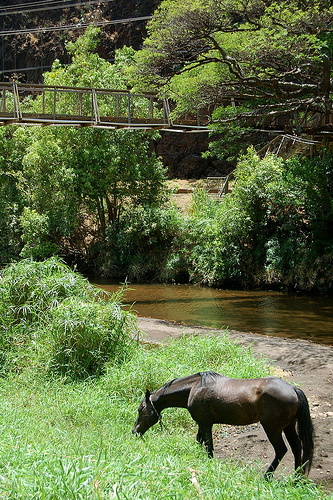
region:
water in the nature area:
[98, 277, 325, 325]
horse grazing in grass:
[131, 375, 323, 482]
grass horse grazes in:
[3, 378, 238, 492]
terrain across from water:
[98, 172, 259, 257]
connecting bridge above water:
[8, 72, 312, 123]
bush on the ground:
[1, 257, 138, 375]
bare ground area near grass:
[147, 328, 332, 465]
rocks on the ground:
[237, 432, 332, 469]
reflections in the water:
[202, 297, 326, 328]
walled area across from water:
[158, 140, 223, 178]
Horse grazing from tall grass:
[120, 371, 315, 482]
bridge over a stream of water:
[11, 82, 239, 128]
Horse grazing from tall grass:
[115, 363, 184, 441]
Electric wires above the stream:
[3, 2, 217, 34]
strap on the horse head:
[145, 389, 168, 444]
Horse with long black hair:
[292, 382, 321, 474]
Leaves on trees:
[146, 7, 314, 184]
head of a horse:
[115, 387, 163, 446]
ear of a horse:
[133, 374, 157, 404]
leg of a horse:
[200, 423, 225, 474]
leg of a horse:
[178, 428, 210, 469]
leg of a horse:
[248, 437, 290, 488]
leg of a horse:
[278, 425, 320, 483]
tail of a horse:
[293, 423, 318, 468]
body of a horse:
[207, 364, 313, 436]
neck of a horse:
[163, 351, 208, 420]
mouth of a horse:
[125, 425, 151, 436]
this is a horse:
[146, 338, 241, 480]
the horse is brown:
[165, 340, 243, 459]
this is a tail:
[274, 386, 331, 464]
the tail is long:
[286, 394, 321, 498]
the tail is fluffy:
[279, 376, 327, 488]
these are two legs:
[242, 434, 318, 485]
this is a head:
[110, 386, 190, 465]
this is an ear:
[117, 356, 155, 400]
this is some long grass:
[64, 429, 137, 490]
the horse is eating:
[131, 362, 183, 431]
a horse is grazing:
[140, 324, 275, 456]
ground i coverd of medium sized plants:
[28, 377, 142, 491]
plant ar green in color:
[37, 411, 119, 497]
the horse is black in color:
[185, 360, 319, 489]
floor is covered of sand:
[293, 353, 330, 405]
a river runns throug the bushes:
[192, 278, 289, 341]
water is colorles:
[167, 278, 247, 325]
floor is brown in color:
[180, 166, 210, 195]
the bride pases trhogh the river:
[67, 75, 185, 131]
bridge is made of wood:
[72, 74, 195, 146]